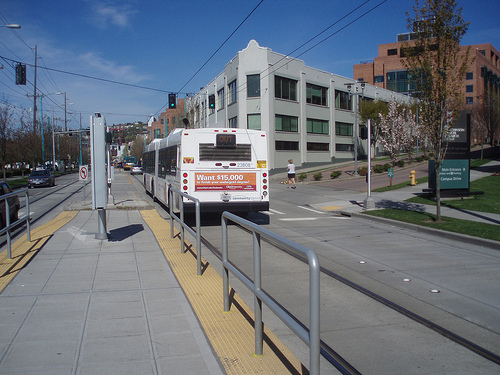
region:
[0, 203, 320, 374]
yellow edges of platform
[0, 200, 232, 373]
gray concrete square tiles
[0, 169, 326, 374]
silver railings on yellow ground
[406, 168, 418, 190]
yellow fire hydrant on sloped sidewalk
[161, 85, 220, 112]
two green lights hanging from wire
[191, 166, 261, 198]
red, orange, and white ad on back of bus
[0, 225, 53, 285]
shadow of railing on ground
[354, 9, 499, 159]
brown brick building next to white building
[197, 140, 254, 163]
black air vents on back of bus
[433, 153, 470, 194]
white letters on green sign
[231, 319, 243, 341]
yellow paint on platform.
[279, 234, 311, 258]
railing on the platform.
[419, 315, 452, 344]
track made of steel.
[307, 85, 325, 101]
window on the building.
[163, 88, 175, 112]
traffic light above street.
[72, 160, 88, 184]
sign on the pole.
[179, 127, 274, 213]
The back of a bus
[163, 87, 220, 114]
Two traffic lights are lit up green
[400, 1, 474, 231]
A tree on the sidewalk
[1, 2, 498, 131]
White clouds in the blue sky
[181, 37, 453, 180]
A large white building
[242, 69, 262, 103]
A window on a building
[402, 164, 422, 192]
A yellow fire hydrant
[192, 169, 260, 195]
A sign on the back of a bus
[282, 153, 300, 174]
Person wearing a white shirt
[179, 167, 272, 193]
Six red rear lights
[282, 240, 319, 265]
railing on the platform.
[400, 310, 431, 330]
track made of steel.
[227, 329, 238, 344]
yellow paint on platform.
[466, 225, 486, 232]
grass on the boulevard.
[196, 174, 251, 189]
banner on the bus.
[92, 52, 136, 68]
clouds in the sky.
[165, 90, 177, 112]
traffic light above the street.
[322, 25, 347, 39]
wires above the tracks.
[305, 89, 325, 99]
window on the building.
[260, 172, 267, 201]
taillights on the bus.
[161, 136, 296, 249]
White bus driving on road.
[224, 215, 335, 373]
Silver railing near road.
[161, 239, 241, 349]
Curb painted yellow near railing.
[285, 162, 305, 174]
Person wearing white shirt.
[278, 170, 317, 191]
Person wearing black shorts.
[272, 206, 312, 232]
White lines marking road.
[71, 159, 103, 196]
Red, white, and black sign on pole.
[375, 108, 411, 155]
Flowers on tree branches.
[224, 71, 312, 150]
Gray building on corner of street.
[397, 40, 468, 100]
Large brick building in distance.